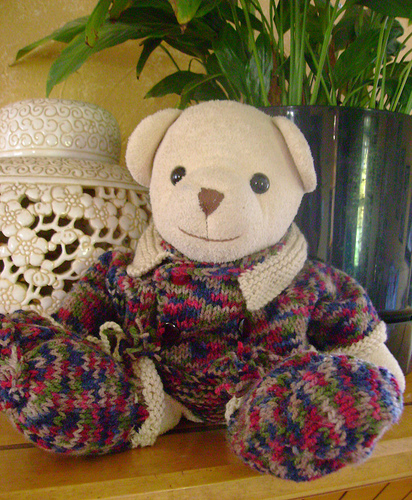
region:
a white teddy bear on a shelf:
[9, 106, 398, 475]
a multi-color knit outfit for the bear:
[7, 231, 406, 485]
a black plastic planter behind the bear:
[260, 108, 411, 372]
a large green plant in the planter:
[20, 3, 409, 112]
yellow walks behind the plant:
[1, 1, 205, 161]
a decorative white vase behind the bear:
[2, 100, 145, 310]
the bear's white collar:
[129, 219, 304, 309]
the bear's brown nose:
[198, 186, 220, 210]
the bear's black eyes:
[171, 167, 268, 191]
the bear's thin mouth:
[178, 227, 238, 240]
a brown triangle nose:
[199, 188, 223, 214]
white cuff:
[330, 322, 387, 356]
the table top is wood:
[1, 375, 410, 497]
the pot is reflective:
[259, 103, 410, 309]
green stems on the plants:
[286, 0, 307, 104]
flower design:
[1, 190, 148, 311]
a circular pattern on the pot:
[1, 100, 118, 159]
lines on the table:
[339, 482, 411, 498]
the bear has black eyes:
[169, 166, 268, 193]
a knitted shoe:
[243, 355, 398, 479]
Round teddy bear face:
[124, 100, 318, 265]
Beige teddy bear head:
[125, 98, 317, 260]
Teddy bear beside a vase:
[1, 97, 404, 480]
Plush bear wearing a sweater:
[0, 99, 411, 482]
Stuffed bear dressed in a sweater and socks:
[2, 98, 404, 480]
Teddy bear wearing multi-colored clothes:
[2, 101, 404, 484]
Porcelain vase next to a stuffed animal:
[0, 99, 404, 482]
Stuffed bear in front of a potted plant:
[1, 0, 409, 480]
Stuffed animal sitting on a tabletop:
[1, 107, 403, 496]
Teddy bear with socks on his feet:
[2, 100, 405, 483]